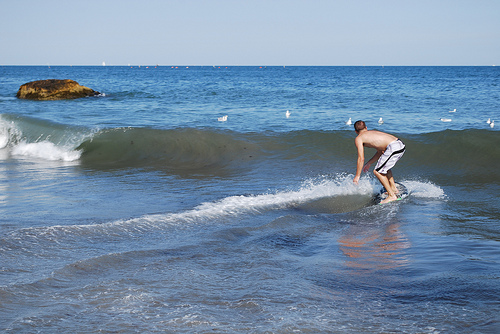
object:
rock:
[4, 67, 105, 106]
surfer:
[342, 117, 409, 208]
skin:
[358, 133, 391, 145]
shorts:
[374, 137, 407, 177]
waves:
[167, 114, 194, 137]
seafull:
[216, 109, 233, 127]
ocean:
[183, 70, 229, 90]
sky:
[95, 18, 133, 42]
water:
[254, 227, 279, 260]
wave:
[107, 122, 131, 145]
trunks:
[374, 142, 405, 172]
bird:
[209, 110, 230, 123]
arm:
[352, 139, 364, 186]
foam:
[30, 137, 50, 163]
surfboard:
[362, 180, 409, 223]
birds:
[272, 106, 294, 120]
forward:
[342, 118, 390, 155]